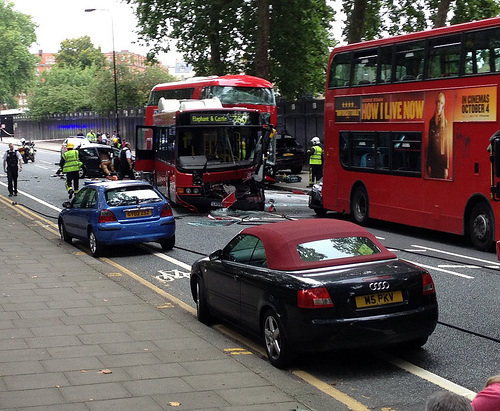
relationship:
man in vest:
[54, 142, 90, 172] [60, 150, 85, 171]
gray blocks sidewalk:
[17, 248, 72, 307] [17, 246, 131, 343]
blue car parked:
[76, 180, 174, 240] [34, 180, 124, 241]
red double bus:
[330, 161, 471, 238] [316, 33, 481, 157]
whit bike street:
[148, 248, 187, 296] [406, 240, 465, 293]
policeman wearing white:
[9, 141, 36, 224] [155, 249, 180, 272]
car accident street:
[76, 180, 174, 240] [406, 240, 465, 293]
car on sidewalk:
[171, 224, 402, 365] [17, 246, 131, 343]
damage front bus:
[185, 175, 266, 193] [316, 33, 481, 157]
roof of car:
[158, 69, 267, 92] [171, 224, 402, 365]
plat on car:
[125, 209, 167, 219] [171, 224, 402, 365]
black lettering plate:
[209, 269, 256, 290] [346, 287, 420, 320]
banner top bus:
[182, 110, 259, 128] [316, 33, 481, 157]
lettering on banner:
[189, 116, 236, 128] [182, 110, 259, 128]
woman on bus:
[197, 132, 248, 180] [316, 33, 481, 157]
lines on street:
[404, 239, 479, 269] [406, 240, 465, 293]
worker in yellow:
[53, 135, 97, 196] [351, 290, 421, 307]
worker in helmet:
[53, 135, 97, 196] [65, 140, 79, 158]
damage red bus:
[185, 175, 266, 193] [316, 33, 481, 157]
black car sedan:
[209, 269, 256, 290] [171, 224, 402, 365]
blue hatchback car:
[76, 180, 174, 240] [171, 224, 402, 365]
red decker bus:
[330, 161, 471, 238] [316, 33, 481, 157]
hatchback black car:
[226, 216, 329, 321] [171, 224, 402, 365]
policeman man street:
[3, 140, 25, 198] [406, 240, 465, 293]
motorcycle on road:
[16, 134, 46, 166] [185, 227, 221, 245]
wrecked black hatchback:
[186, 168, 287, 223] [226, 216, 329, 321]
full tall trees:
[223, 19, 351, 30] [255, 12, 356, 79]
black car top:
[209, 269, 256, 290] [250, 224, 349, 253]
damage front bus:
[185, 175, 262, 211] [316, 33, 481, 157]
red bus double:
[330, 161, 471, 238] [322, 37, 427, 192]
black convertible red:
[209, 269, 256, 290] [330, 161, 471, 238]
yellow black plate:
[351, 290, 421, 307] [346, 287, 420, 320]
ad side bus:
[355, 94, 477, 125] [316, 33, 481, 157]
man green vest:
[54, 142, 90, 172] [60, 150, 85, 171]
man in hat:
[54, 142, 90, 172] [309, 133, 326, 151]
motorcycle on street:
[16, 134, 46, 166] [406, 240, 465, 293]